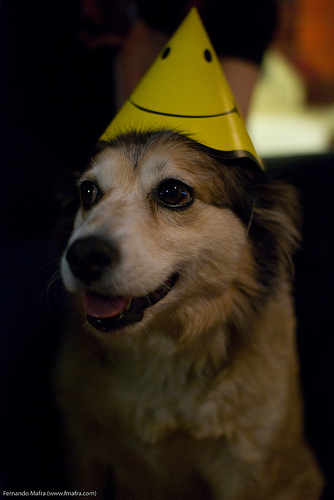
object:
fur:
[108, 150, 128, 172]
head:
[57, 128, 274, 355]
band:
[242, 186, 257, 241]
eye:
[160, 46, 170, 61]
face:
[132, 42, 229, 123]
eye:
[78, 177, 102, 210]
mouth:
[53, 269, 179, 332]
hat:
[92, 3, 262, 171]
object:
[245, 46, 334, 158]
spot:
[202, 48, 211, 64]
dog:
[43, 93, 329, 498]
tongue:
[86, 297, 119, 321]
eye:
[152, 179, 196, 209]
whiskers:
[53, 267, 61, 277]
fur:
[212, 234, 231, 251]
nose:
[63, 236, 111, 283]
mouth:
[128, 99, 236, 124]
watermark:
[1, 488, 97, 497]